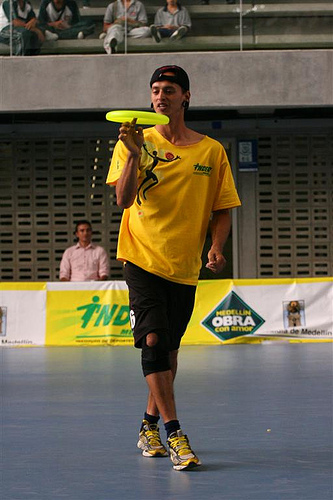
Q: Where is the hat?
A: On the man's head.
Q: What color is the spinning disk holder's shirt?
A: Yellow.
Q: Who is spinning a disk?
A: The man in yellow.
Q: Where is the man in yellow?
A: On a court.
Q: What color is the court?
A: Blue.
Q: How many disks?
A: One.